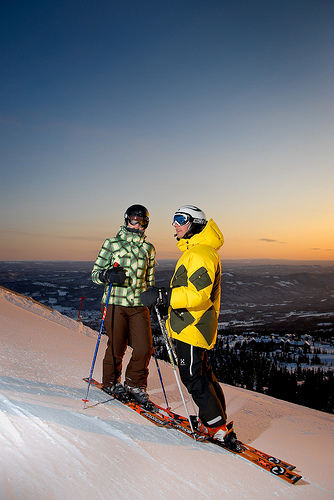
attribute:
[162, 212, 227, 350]
parka — yellow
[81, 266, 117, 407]
ski pole — long , blue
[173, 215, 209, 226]
goggles — Blue , white 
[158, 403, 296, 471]
skis — orange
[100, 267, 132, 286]
glove — black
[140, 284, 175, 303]
glove — black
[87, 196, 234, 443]
people — skiing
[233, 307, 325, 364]
trees — pine, spread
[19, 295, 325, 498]
mountain — slope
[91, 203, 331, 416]
valley — below, pretty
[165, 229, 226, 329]
jacket — yellow, black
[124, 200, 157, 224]
helmet — black 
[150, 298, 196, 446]
skis — orange, black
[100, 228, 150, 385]
outfit — green, pretty, white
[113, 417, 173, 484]
groove — shallow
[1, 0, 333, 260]
sky — bright, blue, clear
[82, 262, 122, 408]
ski pole — blue, red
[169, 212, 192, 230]
goggles — blue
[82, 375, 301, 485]
skis — orange, red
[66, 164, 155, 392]
skier — wearing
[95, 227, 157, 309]
coat — plaid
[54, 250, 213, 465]
skis — orange, black, white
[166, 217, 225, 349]
coat — yellow , black 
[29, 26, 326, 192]
sky — clear 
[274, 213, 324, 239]
sky — orange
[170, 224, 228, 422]
outfit — yellow, checkered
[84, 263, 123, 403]
ski pole — blue, red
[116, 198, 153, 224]
helmet — black